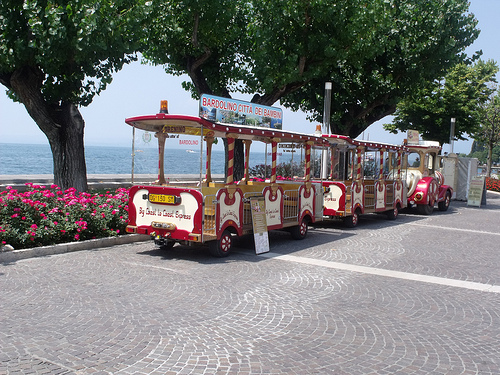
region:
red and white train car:
[4, 125, 482, 292]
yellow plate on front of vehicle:
[128, 187, 182, 208]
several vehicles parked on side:
[10, 125, 462, 276]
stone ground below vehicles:
[90, 232, 344, 350]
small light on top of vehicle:
[134, 97, 192, 125]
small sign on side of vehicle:
[168, 191, 289, 319]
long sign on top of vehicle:
[150, 87, 294, 165]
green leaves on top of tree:
[0, 0, 137, 187]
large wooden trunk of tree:
[24, 75, 116, 176]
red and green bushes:
[8, 180, 83, 241]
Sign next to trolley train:
[246, 190, 273, 261]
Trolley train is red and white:
[126, 113, 423, 234]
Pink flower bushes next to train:
[3, 186, 117, 237]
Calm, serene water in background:
[6, 142, 223, 181]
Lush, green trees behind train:
[3, 2, 497, 95]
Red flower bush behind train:
[486, 171, 498, 193]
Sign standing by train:
[463, 163, 491, 218]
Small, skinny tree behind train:
[466, 100, 499, 157]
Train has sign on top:
[195, 97, 310, 132]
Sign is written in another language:
[194, 86, 294, 130]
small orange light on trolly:
[150, 94, 186, 130]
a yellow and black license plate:
[139, 190, 189, 209]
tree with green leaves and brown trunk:
[0, 55, 140, 167]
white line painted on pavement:
[262, 225, 492, 342]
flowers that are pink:
[0, 171, 132, 262]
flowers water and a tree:
[0, 12, 131, 226]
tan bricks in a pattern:
[40, 290, 427, 374]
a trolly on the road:
[71, 80, 447, 318]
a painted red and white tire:
[195, 228, 251, 273]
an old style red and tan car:
[394, 123, 461, 252]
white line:
[358, 258, 415, 299]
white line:
[315, 262, 472, 357]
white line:
[358, 212, 452, 310]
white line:
[337, 237, 441, 338]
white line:
[338, 255, 419, 313]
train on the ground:
[76, 101, 462, 286]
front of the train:
[118, 157, 215, 247]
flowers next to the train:
[26, 183, 95, 238]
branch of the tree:
[51, 144, 97, 174]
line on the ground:
[366, 248, 426, 299]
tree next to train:
[322, 20, 402, 76]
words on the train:
[128, 193, 204, 230]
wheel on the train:
[436, 186, 466, 215]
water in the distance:
[104, 133, 136, 175]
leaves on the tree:
[278, 13, 340, 60]